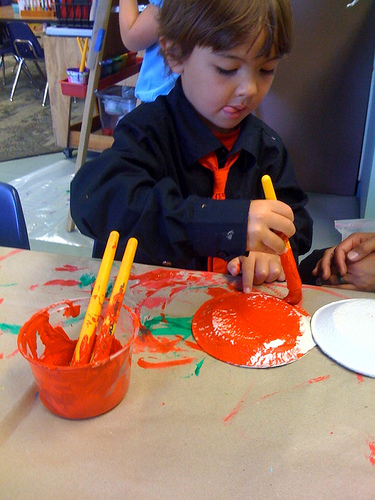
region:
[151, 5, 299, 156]
the person is female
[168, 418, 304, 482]
the table is brown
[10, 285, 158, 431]
the paint is red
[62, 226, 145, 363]
the brushes are yellow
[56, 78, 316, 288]
the jacket is blue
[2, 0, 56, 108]
the chair is blue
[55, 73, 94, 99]
the holder is red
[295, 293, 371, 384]
the plate is white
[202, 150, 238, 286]
the tie is red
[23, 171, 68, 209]
the ground is gray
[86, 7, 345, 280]
child painting a plate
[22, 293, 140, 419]
orange paint in a plastic bowl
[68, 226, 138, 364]
yellow handles of paint brushes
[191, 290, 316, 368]
white paper plate being painted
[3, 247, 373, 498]
brown paper protector on table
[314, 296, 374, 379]
plain white plate laying on table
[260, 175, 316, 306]
paint brush in the child's hand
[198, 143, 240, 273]
orange tie the child is wearing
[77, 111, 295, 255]
right arm of child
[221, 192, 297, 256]
right hand of child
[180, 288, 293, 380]
White plate painted red.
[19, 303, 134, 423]
Clear container painted red.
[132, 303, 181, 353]
Green and red paint.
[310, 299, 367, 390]
White paper plate.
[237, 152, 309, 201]
Tip of yellow paint brush.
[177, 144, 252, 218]
Top of red neck tie.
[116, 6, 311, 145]
Boy with brown hair.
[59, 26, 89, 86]
Paint brushes in a container.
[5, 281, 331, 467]
Paper plates and paints on a table.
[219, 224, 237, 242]
Button on a shirt.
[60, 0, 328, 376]
careful toddler painting paper plate the same color as his tie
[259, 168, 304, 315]
thick yellow paintbrush, bright red paint on its end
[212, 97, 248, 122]
little kid tongue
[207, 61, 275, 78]
little kid has very long, thick eyelashes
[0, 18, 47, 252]
two plastic navy blue backed kindergarten chairs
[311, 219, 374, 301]
an adults clasped hands, with unpainted finternails+wedding ring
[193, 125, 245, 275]
kid's red shirt matches kid's red tie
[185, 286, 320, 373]
red-painted white paper plate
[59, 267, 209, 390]
green paint dabs+splashes+slashes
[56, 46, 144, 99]
several pots of kiddy paint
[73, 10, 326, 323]
a young boy painting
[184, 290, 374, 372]
two paper plates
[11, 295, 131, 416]
a container with orange paint in it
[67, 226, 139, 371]
two yellow handle paint brushes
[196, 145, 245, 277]
an orange tie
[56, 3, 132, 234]
a painting easel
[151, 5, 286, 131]
child with his tongue sticking out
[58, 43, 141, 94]
a tray of different color paints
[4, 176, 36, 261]
part of a blue chair at a table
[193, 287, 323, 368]
painting a paper plate orange